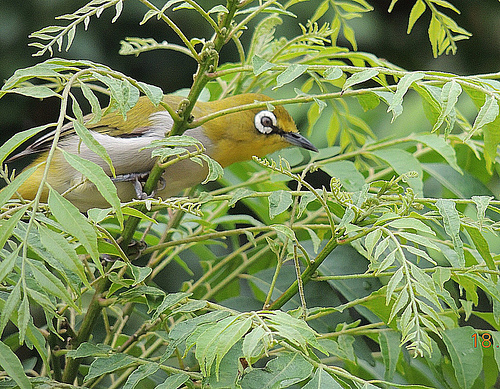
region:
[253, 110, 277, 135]
a white ring around the bird's eye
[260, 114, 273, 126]
the bird's eye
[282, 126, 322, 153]
the bird's black beak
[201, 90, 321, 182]
the head of a bird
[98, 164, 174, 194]
the bird's talons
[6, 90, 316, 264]
a yellow and white bird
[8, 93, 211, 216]
the body of a bird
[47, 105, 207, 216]
a white underside of the bird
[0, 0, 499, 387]
leafy green plants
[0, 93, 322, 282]
a bird on the plant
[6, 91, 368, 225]
A yellow bird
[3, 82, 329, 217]
A yellow bird perched on a green branch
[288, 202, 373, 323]
A green branch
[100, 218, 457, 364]
A bunch of green leaves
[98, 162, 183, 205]
The feet of a bird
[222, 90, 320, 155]
The head of a bird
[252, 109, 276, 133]
The eye of a bird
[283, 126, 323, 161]
The beak of a bird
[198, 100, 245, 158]
The yellow feathers of a bird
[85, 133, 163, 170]
The white feathers of a bird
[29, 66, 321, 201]
a white and yellow bird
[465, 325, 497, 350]
the number eight teen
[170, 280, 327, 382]
green plant leafs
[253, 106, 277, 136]
white and black birds eye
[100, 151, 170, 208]
the birds feet grip the plant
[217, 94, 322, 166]
this bird has a yellow head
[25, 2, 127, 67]
green plant branches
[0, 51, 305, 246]
the bird is hiding in a plant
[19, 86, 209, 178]
the bird has a white belly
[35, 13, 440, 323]
a bird in the bush.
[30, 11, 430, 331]
a pretty bird in the bush.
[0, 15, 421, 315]
a cute little bird in the bush.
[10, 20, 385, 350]
light colored bird in the bush.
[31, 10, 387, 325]
an attractive little bird in the bush.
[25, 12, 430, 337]
a nice bird sitting in the bush.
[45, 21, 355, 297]
a beautiful bird sitting in the bush.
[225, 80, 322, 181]
head of a little bird.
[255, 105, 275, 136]
eye of a little bird.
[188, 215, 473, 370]
green leaves of a bush.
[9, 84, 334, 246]
green bird sitting in tree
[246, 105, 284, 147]
white ring around birds eye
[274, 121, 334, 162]
black beak on green bird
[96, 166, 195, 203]
black claw feet on small bird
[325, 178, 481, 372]
small green leaves on plant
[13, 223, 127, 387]
small green leaves and stem on plant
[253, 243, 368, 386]
small green leaves and stem on plant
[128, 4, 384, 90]
small green leaves on plant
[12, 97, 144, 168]
white and green feathers on bird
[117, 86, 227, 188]
white and green feathers on bird